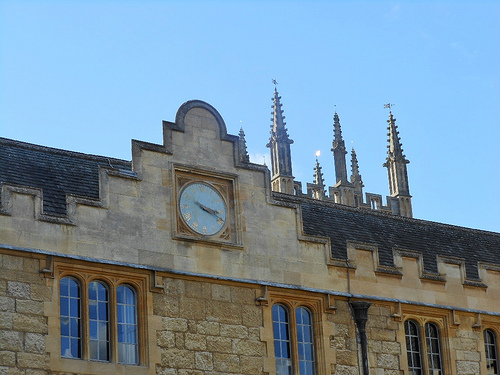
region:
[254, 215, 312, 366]
this is a wall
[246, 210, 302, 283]
the wall is stony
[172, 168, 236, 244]
this is a clock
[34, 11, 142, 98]
this is the sky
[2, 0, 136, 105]
the sky is blue in color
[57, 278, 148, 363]
this is the window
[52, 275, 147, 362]
the window is closed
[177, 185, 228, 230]
the clock is round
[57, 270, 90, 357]
this is a glass window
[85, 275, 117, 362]
this is a glass window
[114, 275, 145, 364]
this is a glass window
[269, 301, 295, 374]
this is a glass window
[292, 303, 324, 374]
this is a glass window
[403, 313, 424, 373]
this is a glass window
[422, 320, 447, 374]
this is a glass window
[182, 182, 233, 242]
this is a clock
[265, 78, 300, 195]
this is a tower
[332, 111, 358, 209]
this is a tower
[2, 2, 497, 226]
The sky above the building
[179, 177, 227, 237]
A clock on the building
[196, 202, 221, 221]
The hands of the clock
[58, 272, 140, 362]
Arched windows on the building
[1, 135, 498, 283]
The roof of the building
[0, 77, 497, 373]
The building has a clock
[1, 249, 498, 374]
The wall of the building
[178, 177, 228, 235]
The clock is circular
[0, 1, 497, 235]
The sky is clear above the building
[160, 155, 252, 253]
Clock on a building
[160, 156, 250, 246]
Clock is on a building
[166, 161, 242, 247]
Clock is on front of a building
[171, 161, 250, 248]
Giant clock on a building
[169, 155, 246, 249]
Giant clock is on a building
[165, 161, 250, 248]
Giant clock on front of a building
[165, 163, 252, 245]
Giant clock is on front of building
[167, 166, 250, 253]
Large clock on a building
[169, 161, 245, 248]
Large clock is on a building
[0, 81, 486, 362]
this is a building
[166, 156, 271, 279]
this is a clock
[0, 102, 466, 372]
clock on a building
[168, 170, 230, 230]
white face of clock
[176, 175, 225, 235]
gold numbers on clock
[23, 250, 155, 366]
3 set of windows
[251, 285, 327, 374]
two set of windows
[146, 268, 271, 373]
tan bricks on building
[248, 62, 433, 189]
multiple steeples in background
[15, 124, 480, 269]
black roof on building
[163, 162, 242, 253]
clock on a buildng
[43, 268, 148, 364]
a row of windows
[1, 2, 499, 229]
blue sky with no clouds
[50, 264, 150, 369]
arched windows in stone wall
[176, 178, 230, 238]
clock with gold numbers on building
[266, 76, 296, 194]
spire on top of building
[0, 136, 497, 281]
black tiled roof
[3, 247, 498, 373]
side of building is stone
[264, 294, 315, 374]
windows reflecting the sky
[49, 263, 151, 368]
windows reflecting sky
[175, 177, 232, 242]
clock shows three twenty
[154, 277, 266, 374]
tan stones on side of building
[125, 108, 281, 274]
clock on the building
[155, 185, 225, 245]
hands on the clock